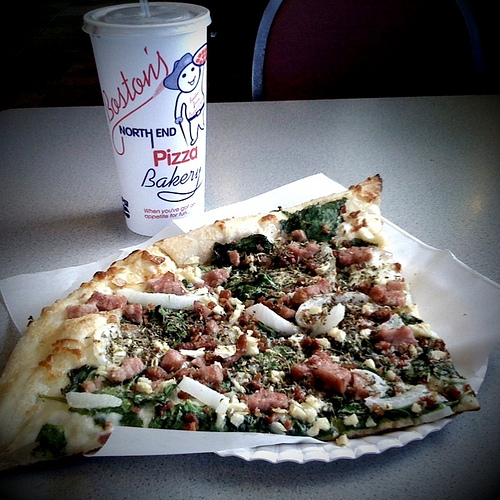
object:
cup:
[78, 3, 213, 239]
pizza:
[1, 176, 480, 458]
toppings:
[91, 209, 459, 432]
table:
[1, 99, 499, 500]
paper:
[9, 174, 350, 336]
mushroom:
[253, 237, 291, 267]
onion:
[176, 377, 227, 413]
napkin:
[84, 426, 329, 457]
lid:
[80, 1, 210, 38]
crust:
[0, 171, 480, 470]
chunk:
[116, 231, 423, 422]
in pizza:
[76, 199, 467, 440]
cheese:
[232, 360, 269, 394]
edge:
[319, 174, 500, 293]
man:
[164, 51, 206, 146]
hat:
[163, 52, 195, 90]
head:
[162, 53, 201, 92]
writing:
[119, 124, 177, 149]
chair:
[251, 0, 489, 105]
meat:
[289, 348, 352, 397]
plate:
[5, 186, 500, 465]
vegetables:
[285, 200, 343, 238]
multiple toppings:
[178, 265, 399, 419]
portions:
[97, 201, 477, 448]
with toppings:
[86, 211, 481, 441]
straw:
[139, 0, 153, 18]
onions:
[130, 291, 197, 307]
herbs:
[233, 268, 266, 299]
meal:
[0, 0, 497, 473]